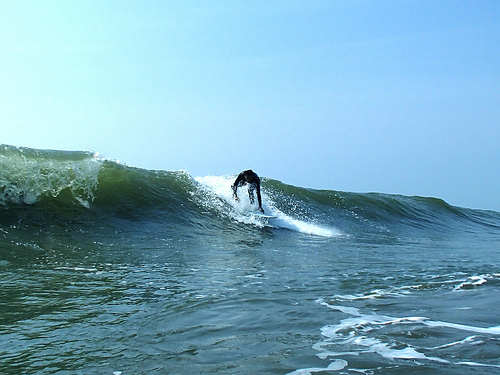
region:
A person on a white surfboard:
[221, 160, 284, 227]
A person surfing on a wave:
[175, 163, 322, 248]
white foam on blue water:
[311, 289, 435, 365]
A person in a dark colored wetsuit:
[220, 168, 281, 226]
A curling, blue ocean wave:
[3, 133, 163, 223]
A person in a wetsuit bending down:
[223, 167, 273, 227]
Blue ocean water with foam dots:
[34, 267, 239, 351]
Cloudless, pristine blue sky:
[197, 20, 428, 116]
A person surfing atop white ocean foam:
[196, 165, 326, 242]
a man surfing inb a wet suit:
[220, 163, 277, 230]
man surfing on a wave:
[225, 162, 270, 227]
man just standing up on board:
[218, 166, 278, 243]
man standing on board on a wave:
[222, 163, 264, 228]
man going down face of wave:
[210, 163, 278, 237]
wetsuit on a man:
[228, 169, 260, 220]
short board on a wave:
[237, 211, 277, 226]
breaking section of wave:
[5, 136, 125, 234]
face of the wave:
[62, 169, 216, 291]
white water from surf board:
[210, 178, 297, 246]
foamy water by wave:
[275, 265, 477, 373]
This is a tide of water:
[8, 145, 65, 228]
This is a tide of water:
[36, 140, 97, 242]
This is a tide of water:
[97, 145, 148, 231]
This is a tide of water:
[150, 149, 192, 229]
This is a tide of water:
[189, 157, 233, 262]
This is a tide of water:
[259, 162, 303, 262]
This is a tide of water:
[299, 166, 347, 271]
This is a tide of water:
[335, 165, 377, 242]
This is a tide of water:
[379, 179, 408, 259]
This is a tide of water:
[399, 171, 456, 244]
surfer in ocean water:
[213, 155, 270, 229]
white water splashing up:
[308, 229, 328, 242]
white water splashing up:
[75, 178, 98, 203]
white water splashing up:
[88, 164, 103, 174]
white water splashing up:
[87, 153, 108, 169]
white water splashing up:
[19, 191, 44, 205]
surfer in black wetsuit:
[212, 158, 271, 225]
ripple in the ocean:
[146, 200, 167, 213]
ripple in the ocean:
[119, 295, 168, 315]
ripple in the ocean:
[50, 309, 97, 333]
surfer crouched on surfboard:
[227, 165, 278, 226]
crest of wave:
[4, 142, 118, 212]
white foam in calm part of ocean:
[302, 275, 498, 371]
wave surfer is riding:
[2, 140, 499, 231]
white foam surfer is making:
[197, 175, 341, 241]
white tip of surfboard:
[245, 206, 281, 226]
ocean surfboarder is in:
[3, 145, 498, 368]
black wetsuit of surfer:
[225, 173, 279, 213]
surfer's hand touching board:
[257, 207, 268, 217]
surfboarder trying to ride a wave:
[207, 160, 282, 230]